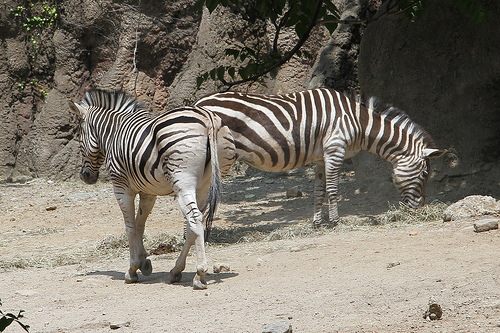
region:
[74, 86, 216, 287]
A zebra is walking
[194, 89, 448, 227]
The zebra is eating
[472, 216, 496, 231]
A rock on the ground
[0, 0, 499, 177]
A wall of stone cliffs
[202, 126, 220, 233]
Tail is hanging down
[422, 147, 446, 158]
Ear is pointed forward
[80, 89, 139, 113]
The mane is striped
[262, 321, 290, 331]
A light colored rock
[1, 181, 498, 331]
Ground covered in dirt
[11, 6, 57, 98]
A plant on the cliff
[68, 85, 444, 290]
Two black and white zebras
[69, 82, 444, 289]
Two striped zebras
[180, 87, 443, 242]
Zebra grazing on grass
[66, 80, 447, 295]
Two zebras standing in the dirt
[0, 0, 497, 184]
Dark natural rock wall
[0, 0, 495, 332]
Two zebras in rocky landscape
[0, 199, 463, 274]
Small line of dried grass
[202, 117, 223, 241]
White and gray zebra tail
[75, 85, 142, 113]
White and black zebra mane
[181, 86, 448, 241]
Zebra eating dry grass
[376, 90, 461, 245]
the zebra is eating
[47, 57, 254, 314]
the zebra is walking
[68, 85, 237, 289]
A zebra on the dirt.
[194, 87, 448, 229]
A zebra eating grass.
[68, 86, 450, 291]
Two zebras standing.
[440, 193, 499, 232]
Two rocks on the ground.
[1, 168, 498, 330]
Sand and rocks on the ground.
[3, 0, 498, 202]
A rocky hill side.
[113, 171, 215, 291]
A zebras four legs.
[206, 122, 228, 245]
A zebras hairy tail.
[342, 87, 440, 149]
A zebras mane on neck.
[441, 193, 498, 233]
Two rocks on the dirt.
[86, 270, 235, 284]
A shadow on the ground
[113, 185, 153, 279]
The front legs of the zebra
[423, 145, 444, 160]
The right ear of the zebra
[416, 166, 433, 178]
The right eye of the zebra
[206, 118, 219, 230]
The tail of the zebra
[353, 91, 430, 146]
The mane of the zebra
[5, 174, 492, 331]
The ground beneath the zebra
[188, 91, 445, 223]
The zebra is eating grass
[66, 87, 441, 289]
Two zebras in an enclosure